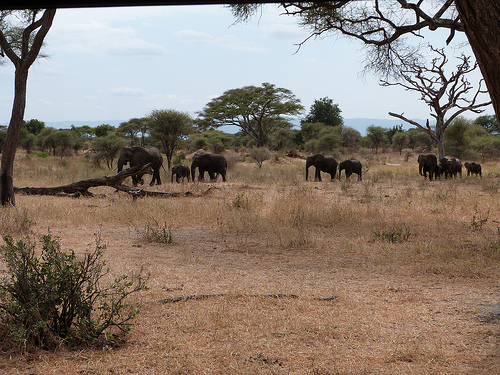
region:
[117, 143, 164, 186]
Elephant leading the herd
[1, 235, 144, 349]
Green bush on ground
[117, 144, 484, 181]
Herd of elephants walking through field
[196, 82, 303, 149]
Large leafy tree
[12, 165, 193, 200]
Fallen tree trunk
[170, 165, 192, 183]
Baby elephant between parents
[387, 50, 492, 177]
Tree with no leaves on it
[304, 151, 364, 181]
Pair of elephants walking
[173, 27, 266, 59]
Fluffy cloud in sky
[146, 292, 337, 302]
Stick in the grass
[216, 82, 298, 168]
tree with green leaves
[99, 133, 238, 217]
two adult elephants and one baby elephant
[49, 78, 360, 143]
sky and trees with green leaves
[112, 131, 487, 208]
elephants walking in a line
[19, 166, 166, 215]
fallen tree trunk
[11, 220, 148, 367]
shrubbery with green leaves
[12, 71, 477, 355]
elephants in Africa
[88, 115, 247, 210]
baby parent between two adult elephants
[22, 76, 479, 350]
elephants walking together on the savanna in Africa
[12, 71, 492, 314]
elephants, trees with leaves and shrubbery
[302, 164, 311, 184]
trunk of an elephant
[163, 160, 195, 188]
a baby elephant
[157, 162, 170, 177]
a tail of an elephant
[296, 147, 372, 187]
an adult elephant and a baby elephant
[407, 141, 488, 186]
a group of elephants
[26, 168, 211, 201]
a tree limb on the ground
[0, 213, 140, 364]
a bush on the ground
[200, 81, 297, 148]
a couple of trees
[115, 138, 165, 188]
a large adult elephant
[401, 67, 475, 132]
a dead tree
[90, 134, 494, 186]
A herd of elephants walking across a field.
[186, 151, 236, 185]
A mother elephant walking next to her baby.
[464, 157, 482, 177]
A baby elephant walking with it's pack.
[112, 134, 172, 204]
A father elephant leading the pack.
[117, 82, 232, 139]
A group of trees in a field.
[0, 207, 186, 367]
A wild green plant near a tree.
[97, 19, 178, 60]
A cloud in a hazy blue sky.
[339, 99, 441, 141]
A mountain range off in the distance.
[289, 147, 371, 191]
A couple of elephants hanging out.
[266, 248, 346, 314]
A patch of really dry grass in a field.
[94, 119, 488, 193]
herd of elephants walking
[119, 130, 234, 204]
baby elephant with two adults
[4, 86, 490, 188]
trees behind herd of elephants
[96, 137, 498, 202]
eight elephants walking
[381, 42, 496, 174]
one completely bare tree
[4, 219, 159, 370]
bush with green leaves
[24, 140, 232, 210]
tree limb in front of three elephants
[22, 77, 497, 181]
one tree taller than rest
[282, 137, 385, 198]
two elephants together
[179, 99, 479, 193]
mountains in background